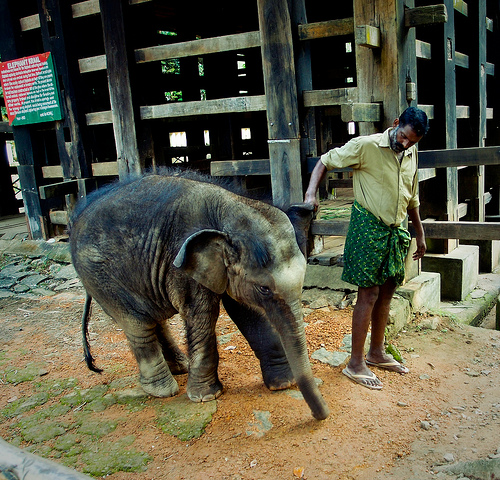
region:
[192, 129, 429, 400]
man beside the baby elephant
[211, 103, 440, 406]
man beside the baby elephant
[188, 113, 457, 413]
man beside the baby elephant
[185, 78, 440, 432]
man beside the baby elephant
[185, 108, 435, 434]
man beside the baby elephant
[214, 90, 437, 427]
man beside the baby elephant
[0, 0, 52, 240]
column on big wooden structure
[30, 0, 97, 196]
column on big wooden structure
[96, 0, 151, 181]
column on big wooden structure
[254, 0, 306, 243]
column on big wooden structure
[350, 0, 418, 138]
column on big wooden structure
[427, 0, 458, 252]
column on big wooden structure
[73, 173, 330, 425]
small elephant looking for food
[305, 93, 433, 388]
man pulling the ear of the elephant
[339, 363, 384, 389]
sandal on the man pulling the elephant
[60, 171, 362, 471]
the elephant is hairy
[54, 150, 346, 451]
the elephant is hairy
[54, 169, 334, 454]
the elephant is hairy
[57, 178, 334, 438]
the elephant is hairy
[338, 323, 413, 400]
man is wearing slippers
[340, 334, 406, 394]
man is wearing slippers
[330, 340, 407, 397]
man is wearing slippers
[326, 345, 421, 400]
man is wearing slippers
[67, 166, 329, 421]
a baby elephant is standing on the ground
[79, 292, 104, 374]
baby elephant has a gray tail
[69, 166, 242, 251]
baby elephant has a fuzzy back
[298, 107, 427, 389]
the man is wearing flip flops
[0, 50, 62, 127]
a red and green sign is hanging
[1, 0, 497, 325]
wooden structure behind the baby elephant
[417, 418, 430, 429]
small rock lying on the ground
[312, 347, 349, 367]
flat stone on ground behind man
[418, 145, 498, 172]
wooden beam next to the man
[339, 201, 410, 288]
man wearing green fabric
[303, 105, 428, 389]
man leading a baby elephant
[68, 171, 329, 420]
a gray baby elephant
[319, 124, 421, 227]
a yellow shirt on the man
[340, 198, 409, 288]
green shorts on the man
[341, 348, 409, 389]
flip flops on the man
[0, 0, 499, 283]
a large wooden structure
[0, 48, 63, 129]
a green and red sign on the structure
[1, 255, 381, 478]
stones on the ground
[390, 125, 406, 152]
white beard on the man's face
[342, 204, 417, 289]
man wearing green sarong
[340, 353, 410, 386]
Indian man wearing flip flops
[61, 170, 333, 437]
baby elephant with Indian man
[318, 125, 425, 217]
Indian man wearing yellow shirt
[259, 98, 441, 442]
the man is looking an elephant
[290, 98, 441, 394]
man wearing flip flops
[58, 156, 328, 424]
elephant has black hair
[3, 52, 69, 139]
a sign on poles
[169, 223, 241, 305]
the ear on the left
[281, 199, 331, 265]
the ear on the right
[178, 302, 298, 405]
front legs of elephant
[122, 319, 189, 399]
back legs of elephant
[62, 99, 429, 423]
Man and elephant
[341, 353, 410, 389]
Flip flops on man's feet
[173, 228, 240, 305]
Elephant's right ear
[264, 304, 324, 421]
Elephant's trunk touching the ground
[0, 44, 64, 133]
Red and green sign on the structure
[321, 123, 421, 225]
Yellow button-down shirt on the man